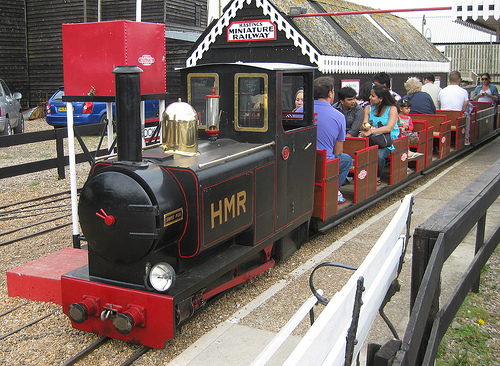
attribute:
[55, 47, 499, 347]
attraction — shaped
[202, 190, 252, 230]
hmr — written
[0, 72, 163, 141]
cars — parked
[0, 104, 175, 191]
fence — separating, black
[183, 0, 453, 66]
roof — sloped, shading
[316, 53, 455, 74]
detailing — white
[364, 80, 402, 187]
woman — brunette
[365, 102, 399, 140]
outfit — turquoise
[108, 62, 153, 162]
smokestack — black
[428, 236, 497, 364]
grass — patchy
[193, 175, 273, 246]
letters — black red gold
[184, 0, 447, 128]
building — brown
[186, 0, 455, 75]
trim — white, gold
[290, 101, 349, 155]
shirt — purple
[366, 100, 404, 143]
shirt — blue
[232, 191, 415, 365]
bench — white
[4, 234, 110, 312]
platform — red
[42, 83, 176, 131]
car — blue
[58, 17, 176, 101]
box — red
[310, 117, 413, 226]
car — red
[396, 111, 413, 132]
shirt — pink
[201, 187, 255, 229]
words — gold, hmr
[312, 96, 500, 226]
seats — red